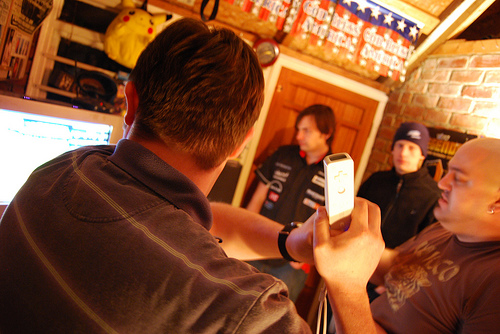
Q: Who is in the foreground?
A: A man.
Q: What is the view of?
A: The person's head.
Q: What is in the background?
A: Tv.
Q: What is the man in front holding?
A: White controller.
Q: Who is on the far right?
A: Bald man.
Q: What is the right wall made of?
A: Red brick.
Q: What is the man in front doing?
A: Playing video game.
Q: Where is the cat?
A: Hanging on back wall.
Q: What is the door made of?
A: Brown wood.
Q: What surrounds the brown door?
A: White wall.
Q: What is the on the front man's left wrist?
A: Black watch.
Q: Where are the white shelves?
A: Against back wall.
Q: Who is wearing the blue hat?
A: Second man from right.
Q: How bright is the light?
A: Very bright.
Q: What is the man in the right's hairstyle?
A: Bald.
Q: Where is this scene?
A: Bar.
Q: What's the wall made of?
A: Bricks.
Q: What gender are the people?
A: Male.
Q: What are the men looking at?
A: TV.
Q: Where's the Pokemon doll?
A: On shelf.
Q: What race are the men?
A: White.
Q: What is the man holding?
A: A wii controller.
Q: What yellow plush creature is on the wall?
A: Pikachu.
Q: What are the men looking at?
A: A TV screen.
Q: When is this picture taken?
A: At night time.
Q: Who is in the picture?
A: Men.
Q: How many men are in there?
A: Four.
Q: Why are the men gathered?
A: To play.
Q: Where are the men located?
A: Around a TV.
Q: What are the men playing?
A: Wii.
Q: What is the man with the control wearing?
A: A polo shirt.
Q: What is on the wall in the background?
A: A banner.